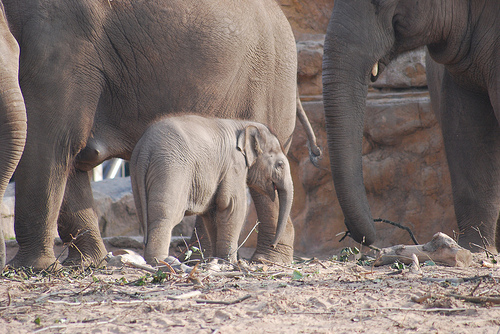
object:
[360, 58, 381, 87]
tusk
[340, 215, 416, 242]
twig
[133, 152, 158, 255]
tail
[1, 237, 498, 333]
ground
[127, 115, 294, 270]
elephant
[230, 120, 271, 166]
ear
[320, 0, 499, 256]
elephant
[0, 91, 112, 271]
legs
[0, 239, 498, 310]
grass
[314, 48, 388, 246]
trunk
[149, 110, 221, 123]
hair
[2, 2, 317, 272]
elephant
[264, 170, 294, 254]
elephant's trunk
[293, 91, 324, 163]
tail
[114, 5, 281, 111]
skin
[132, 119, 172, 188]
behind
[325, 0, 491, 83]
head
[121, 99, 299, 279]
trunk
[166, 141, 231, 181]
dirt